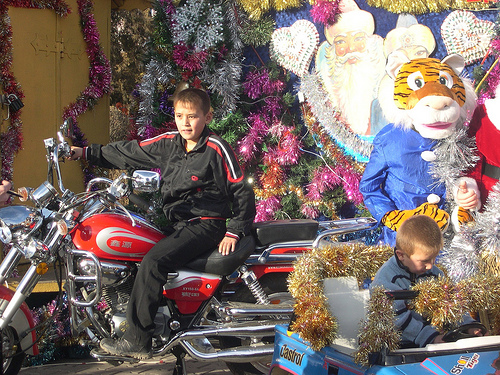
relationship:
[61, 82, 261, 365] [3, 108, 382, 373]
boy sitting on motorcycle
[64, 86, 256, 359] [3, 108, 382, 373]
boy on motorcycle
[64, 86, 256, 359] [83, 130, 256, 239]
boy wears jacket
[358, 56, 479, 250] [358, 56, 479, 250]
mascot wears mascot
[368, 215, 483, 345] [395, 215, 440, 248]
boy has hair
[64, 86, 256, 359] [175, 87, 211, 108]
boy has hair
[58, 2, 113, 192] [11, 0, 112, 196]
pink tinsel on wall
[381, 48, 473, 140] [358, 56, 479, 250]
head on mascot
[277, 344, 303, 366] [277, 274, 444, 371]
black lettering on ride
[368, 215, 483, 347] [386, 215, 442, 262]
boy with hair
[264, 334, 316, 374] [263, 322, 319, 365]
black lettering on blue